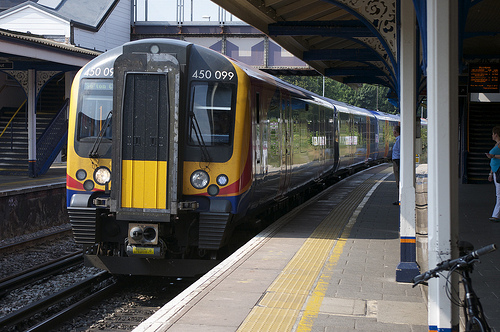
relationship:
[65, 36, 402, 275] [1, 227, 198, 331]
train on track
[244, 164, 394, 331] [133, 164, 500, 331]
stripes on ground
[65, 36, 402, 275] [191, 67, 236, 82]
train lebelled 450 099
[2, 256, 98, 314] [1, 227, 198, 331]
gravel between track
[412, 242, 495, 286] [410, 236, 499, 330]
handlebars of bike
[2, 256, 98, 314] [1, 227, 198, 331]
gravel around track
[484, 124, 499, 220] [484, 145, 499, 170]
woman in shirt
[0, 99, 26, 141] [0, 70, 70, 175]
rail on stairway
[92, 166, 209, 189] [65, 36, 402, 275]
haeadlights on train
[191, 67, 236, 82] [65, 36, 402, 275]
450 099 on train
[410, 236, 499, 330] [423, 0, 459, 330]
bike leaning on pole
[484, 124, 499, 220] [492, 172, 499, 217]
woman wearing pants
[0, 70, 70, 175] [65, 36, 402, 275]
stairway beside train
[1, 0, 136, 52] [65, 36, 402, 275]
building next to train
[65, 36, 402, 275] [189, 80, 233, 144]
train has window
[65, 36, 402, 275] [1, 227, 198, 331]
train in track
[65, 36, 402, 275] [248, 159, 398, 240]
train casting shadow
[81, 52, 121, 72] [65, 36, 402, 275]
reflection on train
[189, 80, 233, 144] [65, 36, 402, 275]
window on train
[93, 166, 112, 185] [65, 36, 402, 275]
light on train